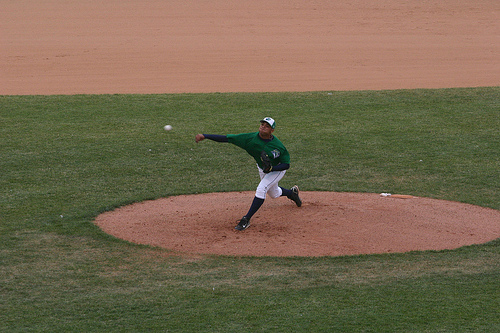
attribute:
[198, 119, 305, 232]
baseball pitcher — pitching, wearing green, professional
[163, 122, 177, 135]
ball — white, in motion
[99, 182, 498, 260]
pitcher mound — dirt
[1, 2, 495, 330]
baseball field — clay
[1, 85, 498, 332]
manicured lawn — short, green, small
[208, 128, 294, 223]
uniform — green, white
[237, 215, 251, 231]
cleat — black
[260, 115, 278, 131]
cap — white, green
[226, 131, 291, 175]
top — green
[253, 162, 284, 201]
pants — white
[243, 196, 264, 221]
sock — black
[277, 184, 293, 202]
sock — black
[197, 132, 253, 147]
arm — extended